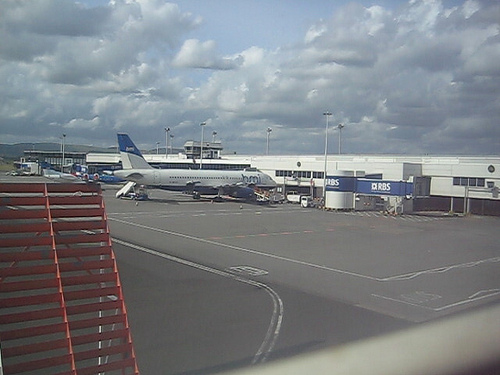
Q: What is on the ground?
A: Plane.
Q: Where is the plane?
A: On the ground.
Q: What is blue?
A: The sky.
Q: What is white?
A: Plane.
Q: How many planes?
A: 1.